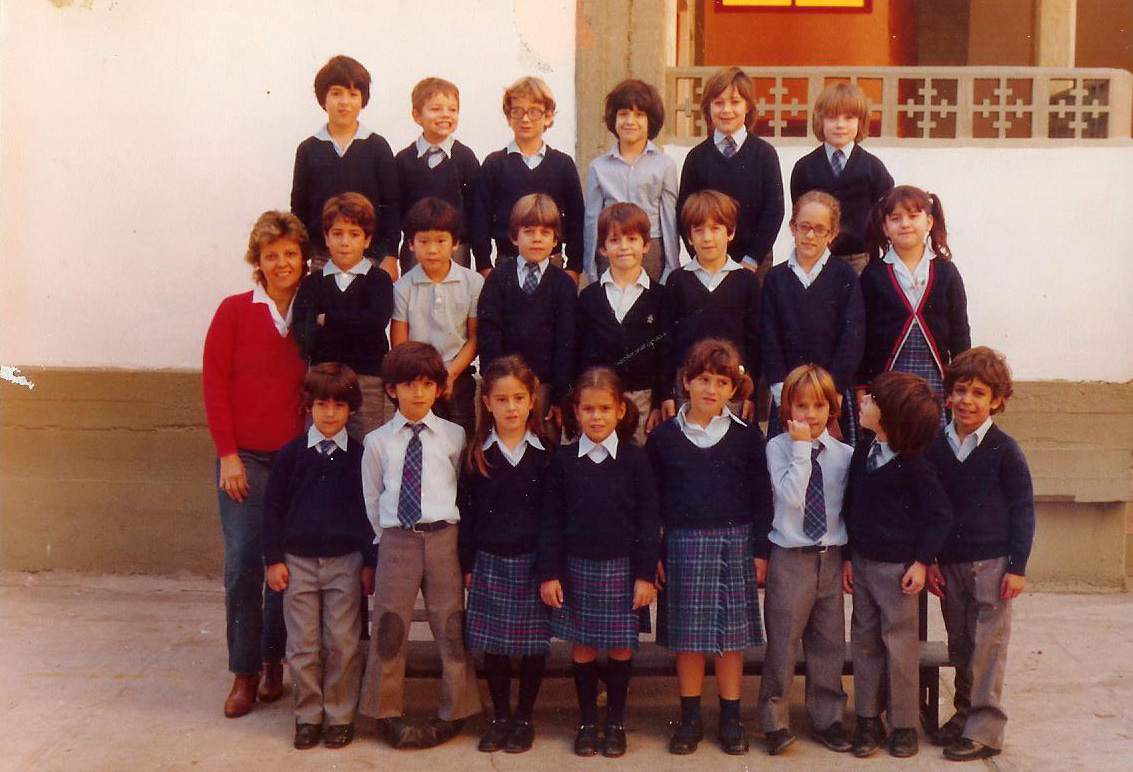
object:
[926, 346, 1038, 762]
kid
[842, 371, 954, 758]
kid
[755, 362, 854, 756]
kid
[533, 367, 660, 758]
kid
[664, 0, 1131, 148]
gate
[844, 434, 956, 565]
sweater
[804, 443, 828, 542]
neck tie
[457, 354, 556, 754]
girl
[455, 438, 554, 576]
sweater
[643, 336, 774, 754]
girl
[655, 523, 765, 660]
skirt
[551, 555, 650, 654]
skirt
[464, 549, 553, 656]
skirt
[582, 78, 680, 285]
boy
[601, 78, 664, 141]
hair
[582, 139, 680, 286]
dress shirt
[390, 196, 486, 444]
boy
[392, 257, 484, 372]
shirt